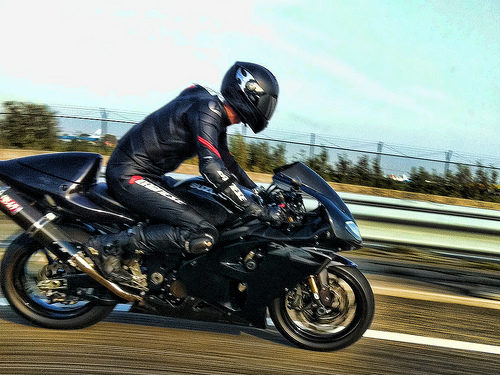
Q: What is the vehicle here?
A: Motorcycle.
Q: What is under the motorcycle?
A: Road.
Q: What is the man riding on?
A: A motorcycle.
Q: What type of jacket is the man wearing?
A: A motorcycle jacket.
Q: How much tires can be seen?
A: Two.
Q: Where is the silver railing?
A: To the left of the man.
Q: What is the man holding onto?
A: Handlebars.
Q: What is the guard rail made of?
A: Metal.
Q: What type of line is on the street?
A: A solid white line.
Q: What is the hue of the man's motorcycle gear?
A: Black.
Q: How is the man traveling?
A: By motorcycle.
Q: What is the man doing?
A: Riding a motorcycle.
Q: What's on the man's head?
A: Helmet.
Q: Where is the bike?
A: Street.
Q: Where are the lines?
A: Street.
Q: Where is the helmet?
A: On the man's head.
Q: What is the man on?
A: Motorcycle.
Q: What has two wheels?
A: Motorcycle.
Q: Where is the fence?
A: By the road.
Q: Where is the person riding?
A: On track.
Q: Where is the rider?
A: On motorcycle.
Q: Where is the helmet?
A: On motorcyclist's head.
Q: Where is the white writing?
A: Rider's outfit.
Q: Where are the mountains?
A: Background.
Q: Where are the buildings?
A: Behind fence.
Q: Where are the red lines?
A: On rider.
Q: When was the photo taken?
A: Daytime.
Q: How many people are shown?
A: One.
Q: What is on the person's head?
A: Helmet.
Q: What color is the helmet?
A: Black.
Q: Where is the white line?
A: Street.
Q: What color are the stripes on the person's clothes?
A: Red.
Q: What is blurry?
A: Background.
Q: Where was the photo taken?
A: On a highway.